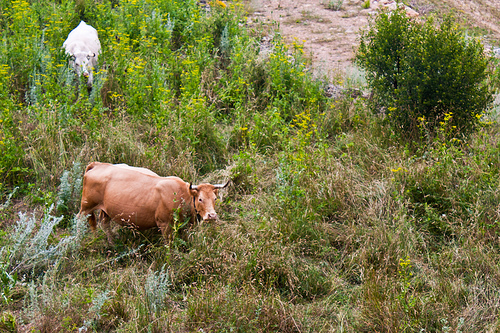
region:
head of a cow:
[171, 174, 242, 224]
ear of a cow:
[183, 181, 208, 196]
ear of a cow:
[212, 182, 236, 192]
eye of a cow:
[191, 193, 204, 203]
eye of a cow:
[208, 194, 228, 204]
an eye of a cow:
[194, 196, 206, 202]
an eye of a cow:
[211, 190, 223, 200]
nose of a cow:
[200, 205, 227, 221]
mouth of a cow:
[202, 208, 225, 221]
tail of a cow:
[74, 156, 91, 183]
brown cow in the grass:
[65, 133, 275, 259]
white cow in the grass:
[63, 26, 110, 73]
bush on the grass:
[351, 29, 495, 124]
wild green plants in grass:
[16, 210, 103, 284]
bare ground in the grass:
[282, 3, 494, 88]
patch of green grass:
[268, 193, 307, 225]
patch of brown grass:
[356, 179, 400, 225]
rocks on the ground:
[281, 21, 343, 44]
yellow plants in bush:
[398, 20, 440, 55]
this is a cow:
[84, 155, 228, 240]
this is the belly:
[107, 185, 147, 217]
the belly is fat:
[101, 187, 152, 217]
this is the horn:
[184, 177, 196, 193]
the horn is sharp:
[186, 180, 198, 191]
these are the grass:
[242, 170, 444, 324]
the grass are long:
[256, 172, 420, 331]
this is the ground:
[319, 16, 349, 39]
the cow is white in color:
[70, 29, 96, 44]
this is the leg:
[80, 198, 96, 219]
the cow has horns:
[63, 160, 233, 245]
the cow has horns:
[169, 161, 239, 233]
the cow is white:
[52, 17, 137, 99]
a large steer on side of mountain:
[78, 159, 229, 249]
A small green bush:
[362, 8, 499, 148]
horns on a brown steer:
[188, 177, 233, 192]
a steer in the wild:
[2, 0, 498, 330]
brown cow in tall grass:
[78, 157, 230, 253]